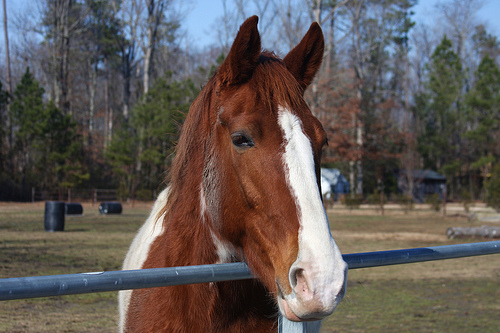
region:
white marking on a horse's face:
[271, 103, 342, 286]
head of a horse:
[191, 10, 356, 326]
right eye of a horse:
[223, 127, 255, 153]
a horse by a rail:
[104, 9, 356, 331]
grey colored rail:
[0, 228, 499, 303]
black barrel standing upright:
[41, 199, 66, 234]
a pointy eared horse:
[119, 14, 353, 329]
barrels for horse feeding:
[29, 194, 130, 239]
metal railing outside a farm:
[2, 220, 496, 331]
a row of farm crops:
[316, 183, 498, 224]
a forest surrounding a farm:
[0, 3, 498, 203]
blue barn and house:
[316, 158, 466, 210]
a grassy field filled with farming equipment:
[2, 208, 497, 330]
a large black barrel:
[43, 197, 68, 231]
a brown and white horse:
[112, 17, 354, 331]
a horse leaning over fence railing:
[115, 14, 356, 331]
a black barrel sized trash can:
[40, 194, 68, 238]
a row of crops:
[320, 180, 498, 217]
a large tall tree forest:
[3, 10, 167, 190]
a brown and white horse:
[103, 10, 348, 324]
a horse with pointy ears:
[105, 5, 370, 330]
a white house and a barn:
[316, 163, 460, 207]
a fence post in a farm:
[2, 234, 499, 331]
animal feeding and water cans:
[62, 197, 132, 219]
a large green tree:
[5, 60, 113, 194]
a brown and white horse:
[116, 13, 352, 331]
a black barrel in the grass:
[41, 198, 68, 235]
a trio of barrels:
[43, 198, 123, 234]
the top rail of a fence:
[1, 236, 499, 304]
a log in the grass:
[444, 221, 499, 247]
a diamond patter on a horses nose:
[266, 99, 353, 324]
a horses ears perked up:
[221, 11, 327, 90]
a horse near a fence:
[116, 11, 349, 331]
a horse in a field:
[116, 11, 349, 331]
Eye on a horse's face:
[227, 130, 252, 151]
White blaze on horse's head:
[277, 108, 332, 270]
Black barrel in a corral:
[44, 198, 65, 233]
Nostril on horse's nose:
[285, 264, 309, 296]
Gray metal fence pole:
[2, 238, 498, 297]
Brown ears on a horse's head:
[231, 14, 325, 84]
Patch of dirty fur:
[203, 158, 223, 220]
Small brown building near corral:
[401, 169, 446, 201]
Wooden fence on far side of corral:
[25, 185, 157, 200]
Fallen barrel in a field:
[97, 200, 124, 214]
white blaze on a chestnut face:
[273, 103, 343, 295]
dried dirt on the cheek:
[198, 128, 227, 250]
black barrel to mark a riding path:
[42, 203, 67, 229]